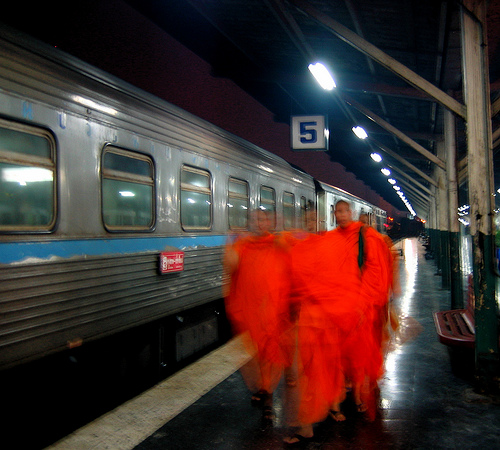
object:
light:
[307, 61, 337, 92]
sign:
[159, 250, 184, 275]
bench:
[428, 273, 479, 366]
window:
[99, 142, 159, 234]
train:
[0, 24, 397, 376]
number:
[298, 121, 319, 145]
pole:
[458, 8, 500, 245]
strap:
[355, 222, 367, 276]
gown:
[289, 226, 346, 403]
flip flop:
[276, 427, 316, 445]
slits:
[431, 310, 462, 343]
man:
[218, 206, 296, 423]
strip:
[0, 234, 237, 266]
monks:
[275, 201, 367, 443]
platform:
[0, 236, 500, 450]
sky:
[0, 0, 382, 210]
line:
[38, 323, 266, 449]